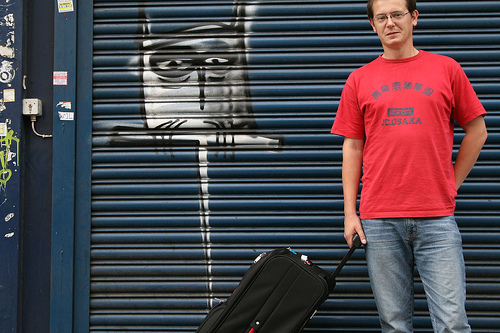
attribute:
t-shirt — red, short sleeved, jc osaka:
[330, 51, 486, 221]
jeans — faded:
[357, 219, 469, 332]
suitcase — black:
[200, 247, 333, 332]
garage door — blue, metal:
[92, 4, 497, 331]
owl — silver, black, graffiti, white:
[138, 1, 255, 134]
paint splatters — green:
[0, 128, 19, 185]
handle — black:
[331, 233, 366, 280]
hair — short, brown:
[366, 1, 415, 15]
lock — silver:
[250, 251, 265, 260]